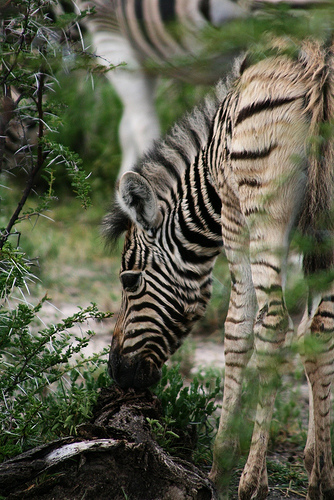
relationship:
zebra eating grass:
[97, 43, 287, 487] [44, 352, 217, 453]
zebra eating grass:
[97, 43, 287, 487] [31, 352, 227, 450]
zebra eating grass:
[97, 43, 287, 487] [21, 346, 222, 466]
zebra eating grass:
[97, 43, 287, 487] [89, 398, 194, 426]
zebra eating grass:
[97, 43, 287, 487] [106, 401, 180, 416]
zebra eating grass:
[97, 43, 287, 487] [105, 398, 170, 403]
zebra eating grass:
[97, 43, 287, 487] [106, 395, 169, 408]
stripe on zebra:
[248, 258, 282, 272] [97, 43, 287, 487]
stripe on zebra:
[240, 204, 272, 223] [97, 43, 287, 487]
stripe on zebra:
[226, 140, 278, 162] [103, 35, 311, 464]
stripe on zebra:
[233, 91, 301, 127] [97, 43, 287, 487]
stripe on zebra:
[225, 360, 246, 368] [97, 43, 287, 487]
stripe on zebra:
[225, 331, 254, 343] [97, 43, 287, 487]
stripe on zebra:
[223, 315, 249, 323] [97, 43, 287, 487]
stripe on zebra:
[124, 309, 172, 344] [97, 43, 287, 487]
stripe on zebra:
[121, 328, 163, 349] [97, 43, 287, 487]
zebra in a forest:
[97, 43, 287, 487] [9, 54, 296, 486]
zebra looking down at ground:
[97, 43, 287, 487] [15, 400, 279, 468]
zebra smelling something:
[97, 43, 287, 487] [107, 401, 163, 408]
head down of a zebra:
[100, 170, 214, 389] [97, 43, 287, 487]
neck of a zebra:
[160, 112, 207, 257] [97, 43, 287, 487]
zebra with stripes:
[97, 43, 287, 487] [151, 267, 194, 319]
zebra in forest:
[97, 43, 287, 487] [0, 0, 334, 500]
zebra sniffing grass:
[97, 43, 287, 487] [0, 382, 218, 499]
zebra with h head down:
[97, 43, 287, 487] [100, 166, 214, 390]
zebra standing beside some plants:
[97, 43, 287, 487] [112, 391, 206, 434]